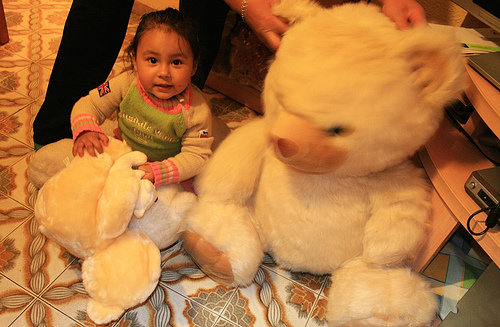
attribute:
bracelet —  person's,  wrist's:
[236, 0, 250, 22]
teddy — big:
[183, 4, 461, 324]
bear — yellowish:
[27, 130, 167, 324]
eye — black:
[321, 121, 348, 135]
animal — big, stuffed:
[202, 8, 443, 322]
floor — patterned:
[1, 0, 491, 325]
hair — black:
[123, 7, 205, 57]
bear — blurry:
[221, 28, 471, 318]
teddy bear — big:
[172, 1, 471, 325]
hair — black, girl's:
[122, 4, 202, 72]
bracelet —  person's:
[238, 4, 256, 23]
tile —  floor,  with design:
[155, 263, 282, 325]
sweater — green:
[58, 70, 267, 217]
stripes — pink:
[149, 159, 179, 189]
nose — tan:
[262, 116, 314, 172]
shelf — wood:
[426, 127, 497, 251]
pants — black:
[30, 2, 225, 146]